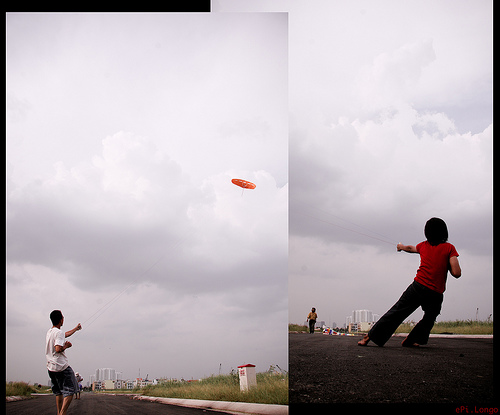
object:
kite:
[227, 176, 257, 194]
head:
[46, 310, 67, 326]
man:
[44, 309, 84, 414]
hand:
[76, 323, 82, 329]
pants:
[361, 273, 442, 346]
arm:
[64, 322, 86, 336]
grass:
[138, 375, 283, 405]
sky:
[9, 3, 494, 312]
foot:
[357, 335, 371, 347]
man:
[356, 213, 463, 352]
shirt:
[414, 241, 457, 292]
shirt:
[46, 327, 70, 374]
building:
[95, 361, 118, 386]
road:
[8, 377, 202, 414]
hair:
[424, 217, 447, 245]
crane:
[217, 359, 224, 379]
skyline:
[142, 368, 287, 382]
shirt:
[307, 310, 319, 321]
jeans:
[49, 369, 80, 396]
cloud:
[33, 209, 241, 298]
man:
[304, 305, 320, 335]